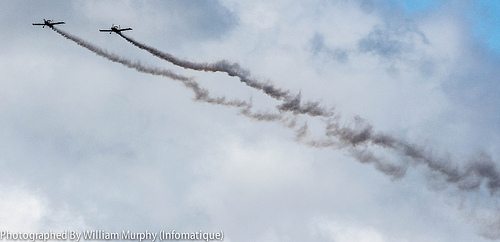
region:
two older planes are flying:
[31, 18, 133, 35]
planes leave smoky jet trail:
[51, 24, 498, 240]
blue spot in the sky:
[393, 0, 499, 61]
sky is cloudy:
[0, 0, 499, 240]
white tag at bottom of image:
[1, 227, 226, 239]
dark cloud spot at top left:
[1, 0, 241, 52]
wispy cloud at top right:
[308, 0, 434, 80]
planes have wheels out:
[42, 23, 113, 34]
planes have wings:
[31, 20, 131, 31]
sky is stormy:
[0, 0, 499, 240]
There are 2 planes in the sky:
[26, 15, 246, 101]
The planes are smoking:
[32, 13, 404, 151]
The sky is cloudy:
[20, 17, 377, 188]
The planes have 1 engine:
[31, 9, 182, 109]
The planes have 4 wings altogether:
[22, 14, 254, 96]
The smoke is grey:
[73, 35, 446, 182]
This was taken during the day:
[52, 9, 387, 146]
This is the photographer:
[0, 211, 237, 238]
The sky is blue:
[395, 0, 498, 98]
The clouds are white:
[56, 67, 347, 231]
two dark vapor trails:
[17, 12, 270, 136]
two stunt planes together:
[12, 12, 179, 94]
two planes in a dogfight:
[8, 7, 203, 117]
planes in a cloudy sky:
[29, 9, 411, 193]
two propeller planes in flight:
[22, 12, 171, 109]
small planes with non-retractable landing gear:
[8, 5, 174, 140]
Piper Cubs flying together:
[8, 7, 186, 147]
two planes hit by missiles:
[8, 5, 250, 111]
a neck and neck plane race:
[15, 5, 175, 155]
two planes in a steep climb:
[23, 2, 435, 203]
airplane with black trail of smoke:
[31, 12, 67, 32]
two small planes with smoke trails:
[31, 10, 495, 214]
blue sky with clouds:
[1, 2, 498, 239]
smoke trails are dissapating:
[96, 20, 496, 231]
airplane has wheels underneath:
[31, 12, 67, 32]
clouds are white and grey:
[0, 0, 499, 240]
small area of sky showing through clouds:
[385, 1, 499, 55]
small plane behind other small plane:
[101, 22, 131, 41]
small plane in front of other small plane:
[31, 16, 66, 33]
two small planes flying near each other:
[27, 12, 142, 42]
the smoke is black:
[127, 37, 497, 202]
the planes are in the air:
[41, 16, 136, 41]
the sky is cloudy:
[61, 120, 296, 190]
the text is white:
[7, 221, 194, 236]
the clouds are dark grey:
[2, 6, 497, 221]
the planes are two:
[35, 11, 185, 81]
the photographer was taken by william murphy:
[0, 220, 217, 236]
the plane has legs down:
[27, 5, 132, 65]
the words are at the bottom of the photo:
[1, 220, 216, 236]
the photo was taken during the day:
[7, 8, 489, 238]